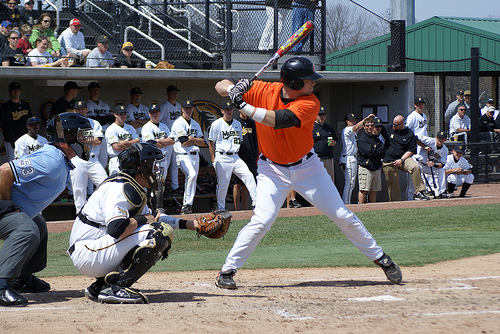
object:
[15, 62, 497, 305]
game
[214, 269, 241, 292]
foot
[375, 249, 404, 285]
foot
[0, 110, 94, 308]
man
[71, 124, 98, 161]
face protection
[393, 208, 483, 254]
grass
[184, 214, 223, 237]
hand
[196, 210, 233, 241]
mitt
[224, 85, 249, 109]
gloves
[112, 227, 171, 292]
shin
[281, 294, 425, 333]
dirt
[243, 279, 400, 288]
shadow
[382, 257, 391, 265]
logo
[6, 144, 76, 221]
jersey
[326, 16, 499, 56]
roof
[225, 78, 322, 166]
jersey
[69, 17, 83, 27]
cap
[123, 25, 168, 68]
railing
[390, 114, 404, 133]
head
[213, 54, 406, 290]
batter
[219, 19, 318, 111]
bat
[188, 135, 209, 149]
arms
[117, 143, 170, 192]
helmet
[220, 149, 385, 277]
pants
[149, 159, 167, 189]
face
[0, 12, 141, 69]
crowd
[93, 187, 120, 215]
white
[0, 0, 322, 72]
bleachers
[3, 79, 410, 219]
dugout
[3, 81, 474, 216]
team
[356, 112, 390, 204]
coaches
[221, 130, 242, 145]
logo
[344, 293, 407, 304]
plate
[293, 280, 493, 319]
ground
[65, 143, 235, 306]
person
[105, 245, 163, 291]
shin guards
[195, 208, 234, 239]
glove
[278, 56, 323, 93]
helmet